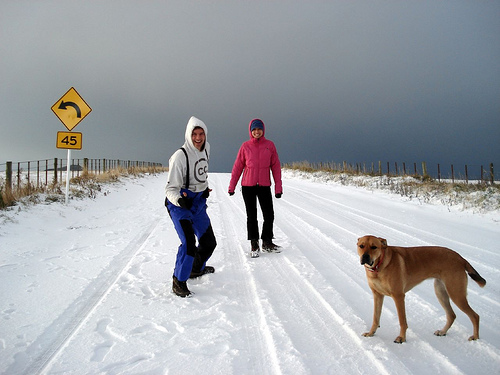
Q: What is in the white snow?
A: Brown dog.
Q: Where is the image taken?
A: In snow.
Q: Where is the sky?
A: Overcast.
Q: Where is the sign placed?
A: Side to the snow.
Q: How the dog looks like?
A: Unhappy.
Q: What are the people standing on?
A: Snow.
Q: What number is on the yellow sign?
A: 45.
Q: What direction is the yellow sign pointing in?
A: Left.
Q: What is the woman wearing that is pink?
A: Coat.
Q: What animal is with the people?
A: Dog.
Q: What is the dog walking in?
A: Snow.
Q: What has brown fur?
A: Dog.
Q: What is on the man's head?
A: Hood.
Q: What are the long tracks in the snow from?
A: Tires.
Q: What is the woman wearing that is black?
A: Pants.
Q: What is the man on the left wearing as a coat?
A: Hoodie.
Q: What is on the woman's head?
A: Blue hat.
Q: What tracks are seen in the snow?
A: Tire tracks.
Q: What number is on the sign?
A: 45.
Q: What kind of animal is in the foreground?
A: Dog.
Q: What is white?
A: The snow.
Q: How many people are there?
A: Two.